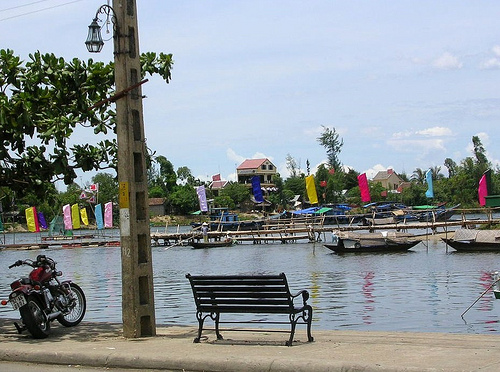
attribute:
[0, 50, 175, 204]
tree branch — leafy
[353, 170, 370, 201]
flag — red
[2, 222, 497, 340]
water — lake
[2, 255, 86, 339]
bike — parked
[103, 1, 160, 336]
pole — concrete, grey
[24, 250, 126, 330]
plate — license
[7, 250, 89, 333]
motorcycle — red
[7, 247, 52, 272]
bars — handle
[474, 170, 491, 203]
banner — pink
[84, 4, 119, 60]
lamp — black, street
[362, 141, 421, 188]
roof — grey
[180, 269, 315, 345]
bench — metal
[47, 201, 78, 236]
flag — pink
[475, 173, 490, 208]
banner — colorful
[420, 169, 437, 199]
banner — colorful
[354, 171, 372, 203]
banner — colorful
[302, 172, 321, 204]
banner — colorful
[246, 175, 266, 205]
banner — colorful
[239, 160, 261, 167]
roof — red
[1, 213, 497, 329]
water — calm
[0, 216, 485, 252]
pier — long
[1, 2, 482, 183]
sky — cloudy